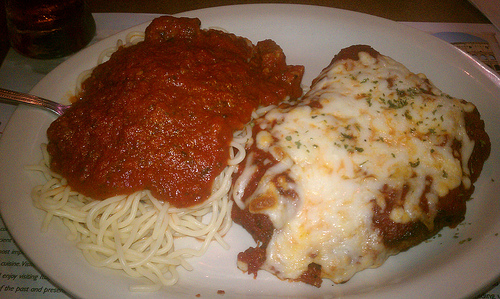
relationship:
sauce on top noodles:
[39, 11, 310, 208] [24, 25, 289, 290]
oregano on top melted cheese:
[287, 76, 446, 173] [242, 48, 480, 292]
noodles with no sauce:
[24, 25, 289, 290] [39, 11, 310, 208]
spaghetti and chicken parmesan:
[31, 10, 250, 278] [242, 48, 480, 292]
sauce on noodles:
[39, 11, 310, 208] [24, 25, 289, 290]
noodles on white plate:
[24, 25, 289, 290] [18, 13, 498, 296]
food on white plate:
[32, 9, 492, 290] [18, 13, 498, 296]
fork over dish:
[3, 87, 71, 113] [18, 13, 498, 296]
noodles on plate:
[31, 10, 250, 278] [18, 13, 498, 296]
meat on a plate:
[150, 9, 285, 66] [18, 13, 498, 296]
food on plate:
[32, 9, 492, 290] [18, 13, 498, 296]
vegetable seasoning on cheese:
[287, 76, 446, 173] [242, 48, 480, 292]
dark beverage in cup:
[2, 4, 102, 64] [0, 2, 99, 65]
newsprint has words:
[2, 234, 60, 298] [2, 234, 60, 298]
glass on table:
[0, 2, 99, 65] [14, 10, 490, 296]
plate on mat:
[18, 13, 498, 296] [18, 13, 498, 296]